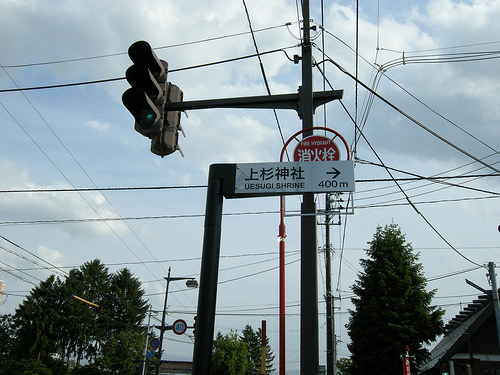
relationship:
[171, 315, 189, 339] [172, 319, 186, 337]
number on sign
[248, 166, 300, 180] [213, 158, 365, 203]
text on sign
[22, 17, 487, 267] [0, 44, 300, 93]
sky has cable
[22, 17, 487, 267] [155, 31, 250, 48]
sky has line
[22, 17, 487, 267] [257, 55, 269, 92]
sky has line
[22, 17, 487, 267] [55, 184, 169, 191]
sky has line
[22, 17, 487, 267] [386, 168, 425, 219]
sky has line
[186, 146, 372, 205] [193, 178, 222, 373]
sign hanging on pole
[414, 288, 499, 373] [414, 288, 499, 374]
building has building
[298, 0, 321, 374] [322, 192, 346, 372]
pole in between pole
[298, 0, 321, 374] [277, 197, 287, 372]
pole in between pole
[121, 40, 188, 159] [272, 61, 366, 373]
traffic light in pole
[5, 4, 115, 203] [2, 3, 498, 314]
clouds in sky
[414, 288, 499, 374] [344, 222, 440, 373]
building near tree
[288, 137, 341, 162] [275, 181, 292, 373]
sign on pole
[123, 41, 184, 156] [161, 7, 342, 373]
traffic light on pole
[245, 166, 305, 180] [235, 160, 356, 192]
text are on sign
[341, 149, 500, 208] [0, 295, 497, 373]
line are above street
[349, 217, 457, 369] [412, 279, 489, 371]
tree next to building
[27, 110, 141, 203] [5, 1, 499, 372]
clouds are in sky